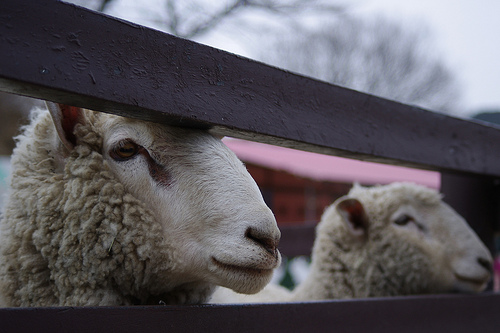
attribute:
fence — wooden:
[1, 0, 498, 175]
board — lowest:
[4, 292, 495, 330]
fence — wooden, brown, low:
[2, 0, 499, 332]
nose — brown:
[240, 216, 298, 261]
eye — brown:
[87, 137, 153, 171]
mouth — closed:
[208, 254, 281, 296]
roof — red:
[210, 120, 460, 205]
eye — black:
[106, 131, 162, 178]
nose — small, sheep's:
[219, 208, 301, 295]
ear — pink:
[49, 98, 82, 151]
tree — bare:
[262, 9, 480, 103]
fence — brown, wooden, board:
[124, 44, 456, 320]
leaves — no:
[325, 26, 443, 88]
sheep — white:
[0, 56, 498, 326]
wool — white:
[0, 105, 210, 309]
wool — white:
[287, 174, 442, 298]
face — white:
[94, 109, 281, 292]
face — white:
[389, 197, 494, 288]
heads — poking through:
[46, 104, 496, 299]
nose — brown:
[243, 200, 285, 260]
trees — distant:
[98, 0, 467, 110]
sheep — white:
[6, 92, 283, 308]